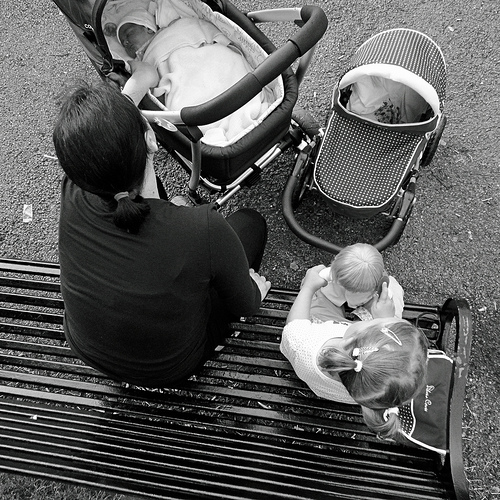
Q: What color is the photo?
A: Black and White.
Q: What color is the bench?
A: Black.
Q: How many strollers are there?
A: Two.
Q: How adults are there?
A: One.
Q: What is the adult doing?
A: Touching the baby.